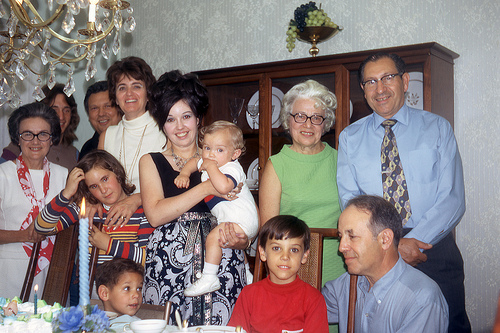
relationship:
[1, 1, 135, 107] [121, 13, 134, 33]
chandelier with crystal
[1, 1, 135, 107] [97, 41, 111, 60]
chandelier with crystal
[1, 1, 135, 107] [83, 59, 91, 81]
chandelier with crystal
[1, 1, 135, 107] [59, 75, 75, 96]
chandelier with crystal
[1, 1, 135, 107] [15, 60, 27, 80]
chandelier with crystal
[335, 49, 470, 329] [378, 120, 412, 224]
man wearing necktie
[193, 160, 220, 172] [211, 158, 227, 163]
hand in mouth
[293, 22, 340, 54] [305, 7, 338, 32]
bowl has grapes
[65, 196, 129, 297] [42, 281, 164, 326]
candle on cake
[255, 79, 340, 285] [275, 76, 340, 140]
woman has grey hair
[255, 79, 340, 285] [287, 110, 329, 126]
woman has glasses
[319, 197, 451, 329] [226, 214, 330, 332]
man looking at boy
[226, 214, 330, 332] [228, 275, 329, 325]
boy in red shirt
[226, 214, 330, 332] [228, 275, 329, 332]
boy has on red shirt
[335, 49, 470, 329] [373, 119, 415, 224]
man wearing tie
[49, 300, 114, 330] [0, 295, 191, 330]
flowers on table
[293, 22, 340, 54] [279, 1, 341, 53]
bowl has grapes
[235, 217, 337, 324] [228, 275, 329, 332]
boy wearing red shirt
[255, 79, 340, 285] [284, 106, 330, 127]
woman wearing glasses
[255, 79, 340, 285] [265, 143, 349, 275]
woman wearing green dress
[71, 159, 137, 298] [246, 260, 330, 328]
girl wearing shirt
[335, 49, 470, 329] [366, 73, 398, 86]
man wearing glasses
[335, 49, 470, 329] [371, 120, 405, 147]
man wearing necktie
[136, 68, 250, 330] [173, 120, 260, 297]
woman holding baby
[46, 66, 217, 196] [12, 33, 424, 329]
people in dining room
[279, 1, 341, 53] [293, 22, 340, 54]
grapes hanging from bowl